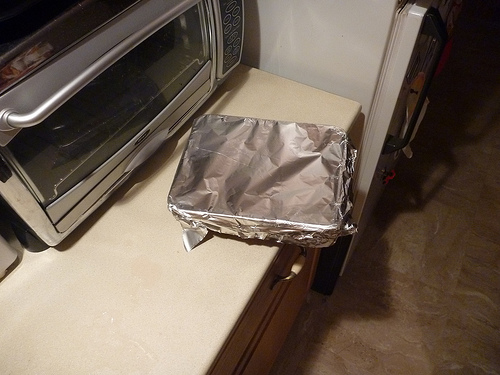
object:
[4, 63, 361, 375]
counter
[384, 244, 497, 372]
tiles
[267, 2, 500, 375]
floor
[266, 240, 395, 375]
shadow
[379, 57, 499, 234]
shadow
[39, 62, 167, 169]
reflection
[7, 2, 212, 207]
glass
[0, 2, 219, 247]
door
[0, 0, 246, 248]
appliance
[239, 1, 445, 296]
appliance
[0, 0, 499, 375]
kitchen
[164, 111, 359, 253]
aluminum foil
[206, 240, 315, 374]
cabinet drawer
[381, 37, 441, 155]
handle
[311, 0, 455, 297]
refrigerator door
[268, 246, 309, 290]
drawer pull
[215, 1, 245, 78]
control panel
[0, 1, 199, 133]
door handle